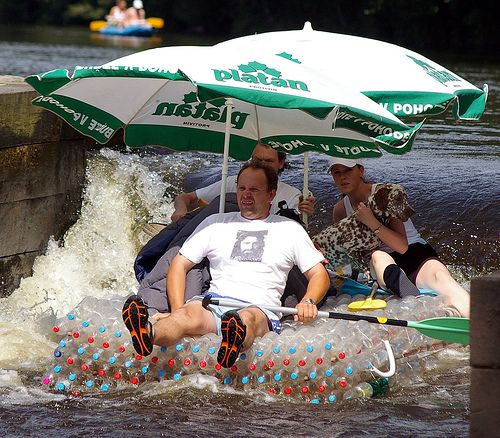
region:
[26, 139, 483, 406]
people rafting on boat made of plastic bottles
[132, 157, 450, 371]
man holding paddle in left hand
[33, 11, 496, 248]
umbrellas attached to rafting boat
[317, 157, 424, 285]
woman holds dalmatian dog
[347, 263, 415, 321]
yellow pad sitting on raft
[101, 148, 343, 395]
man wearing snickers with black and red soles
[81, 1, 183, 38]
raft with people in background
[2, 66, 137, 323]
raft is passing a concrete wall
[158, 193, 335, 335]
man wearing white t-shirt with black print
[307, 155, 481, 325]
woman wearing dark shorts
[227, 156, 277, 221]
the head of a man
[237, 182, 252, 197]
the nose of a man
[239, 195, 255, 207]
the mouth of a man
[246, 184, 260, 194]
the eye of a man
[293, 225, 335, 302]
the arm of a man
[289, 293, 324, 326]
the hand of a man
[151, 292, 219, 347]
the leg of a man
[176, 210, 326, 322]
a white tee shirt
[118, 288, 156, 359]
a black and orange shoe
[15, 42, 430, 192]
a white and green umbrella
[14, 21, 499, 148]
Large white and green umbrellas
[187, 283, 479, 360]
A green water paddle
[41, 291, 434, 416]
A large water raft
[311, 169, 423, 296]
A brown and white spotted dog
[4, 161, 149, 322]
A couple water white caps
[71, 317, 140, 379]
Blue and red tiny circles on the raft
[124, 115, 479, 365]
A group of people rafting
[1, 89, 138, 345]
A large brick wall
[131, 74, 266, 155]
An advertisement on the umbrella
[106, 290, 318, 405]
Orange and black soles on the man's sheos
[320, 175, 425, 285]
Dalmatian dog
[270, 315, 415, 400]
Raft made of plastic bottles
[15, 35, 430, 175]
green and white umbrella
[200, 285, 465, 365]
green and silver raft oar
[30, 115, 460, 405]
three people on a raft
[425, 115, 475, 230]
Rushing river water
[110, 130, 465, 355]
two men and a young woman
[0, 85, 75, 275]
Brick wall or platform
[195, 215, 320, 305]
white t-shirt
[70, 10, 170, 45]
Blue raft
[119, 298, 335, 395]
Orange coloring on the bottom of man's shoes.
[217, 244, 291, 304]
Man wearing white shirt.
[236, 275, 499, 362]
Man holding paddle with green end.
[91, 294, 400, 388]
Man sitting on raft made out of bottles.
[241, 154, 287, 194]
Man has brown hair.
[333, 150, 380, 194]
Person wearing white hat.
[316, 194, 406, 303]
Brown and white dog on raft.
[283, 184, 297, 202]
Man wearing white shirt.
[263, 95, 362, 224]
Green and white umbrella shading people.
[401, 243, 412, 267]
Woman wearing black shorts.